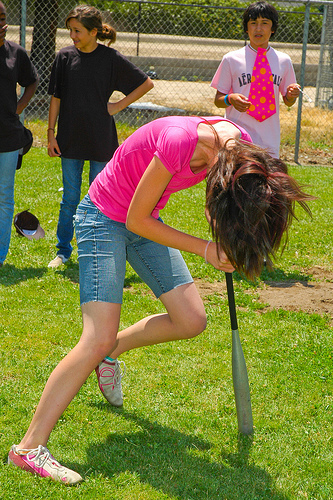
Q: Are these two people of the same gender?
A: No, they are both male and female.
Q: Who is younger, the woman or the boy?
A: The boy is younger than the woman.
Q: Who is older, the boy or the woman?
A: The woman is older than the boy.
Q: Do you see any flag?
A: No, there are no flags.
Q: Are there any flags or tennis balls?
A: No, there are no flags or tennis balls.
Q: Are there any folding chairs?
A: No, there are no folding chairs.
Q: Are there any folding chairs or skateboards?
A: No, there are no folding chairs or skateboards.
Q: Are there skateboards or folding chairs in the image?
A: No, there are no folding chairs or skateboards.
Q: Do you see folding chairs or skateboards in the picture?
A: No, there are no folding chairs or skateboards.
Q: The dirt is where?
A: The dirt is in the grass.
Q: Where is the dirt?
A: The dirt is in the grass.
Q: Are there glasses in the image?
A: No, there are no glasses.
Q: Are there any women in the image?
A: Yes, there is a woman.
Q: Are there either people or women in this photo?
A: Yes, there is a woman.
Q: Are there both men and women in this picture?
A: No, there is a woman but no men.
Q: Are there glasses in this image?
A: No, there are no glasses.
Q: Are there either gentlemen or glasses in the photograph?
A: No, there are no glasses or gentlemen.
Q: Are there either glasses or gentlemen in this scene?
A: No, there are no glasses or gentlemen.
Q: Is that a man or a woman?
A: That is a woman.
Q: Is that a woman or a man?
A: That is a woman.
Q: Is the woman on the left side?
A: Yes, the woman is on the left of the image.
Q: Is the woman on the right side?
A: No, the woman is on the left of the image.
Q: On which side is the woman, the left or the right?
A: The woman is on the left of the image.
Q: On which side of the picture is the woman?
A: The woman is on the left of the image.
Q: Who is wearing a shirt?
A: The woman is wearing a shirt.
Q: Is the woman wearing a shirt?
A: Yes, the woman is wearing a shirt.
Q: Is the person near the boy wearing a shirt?
A: Yes, the woman is wearing a shirt.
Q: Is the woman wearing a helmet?
A: No, the woman is wearing a shirt.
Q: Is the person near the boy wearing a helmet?
A: No, the woman is wearing a shirt.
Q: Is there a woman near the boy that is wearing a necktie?
A: Yes, there is a woman near the boy.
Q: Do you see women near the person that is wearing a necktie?
A: Yes, there is a woman near the boy.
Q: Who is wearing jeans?
A: The woman is wearing jeans.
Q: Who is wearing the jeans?
A: The woman is wearing jeans.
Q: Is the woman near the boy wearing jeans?
A: Yes, the woman is wearing jeans.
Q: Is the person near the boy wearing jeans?
A: Yes, the woman is wearing jeans.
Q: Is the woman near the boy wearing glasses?
A: No, the woman is wearing jeans.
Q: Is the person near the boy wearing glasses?
A: No, the woman is wearing jeans.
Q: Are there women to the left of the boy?
A: Yes, there is a woman to the left of the boy.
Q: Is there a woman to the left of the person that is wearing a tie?
A: Yes, there is a woman to the left of the boy.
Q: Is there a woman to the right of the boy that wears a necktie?
A: No, the woman is to the left of the boy.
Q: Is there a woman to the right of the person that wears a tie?
A: No, the woman is to the left of the boy.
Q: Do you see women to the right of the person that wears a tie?
A: No, the woman is to the left of the boy.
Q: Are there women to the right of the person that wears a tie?
A: No, the woman is to the left of the boy.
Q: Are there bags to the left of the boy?
A: No, there is a woman to the left of the boy.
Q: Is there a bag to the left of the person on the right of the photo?
A: No, there is a woman to the left of the boy.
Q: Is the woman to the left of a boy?
A: Yes, the woman is to the left of a boy.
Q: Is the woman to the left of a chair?
A: No, the woman is to the left of a boy.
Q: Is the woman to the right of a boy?
A: No, the woman is to the left of a boy.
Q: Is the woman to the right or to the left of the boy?
A: The woman is to the left of the boy.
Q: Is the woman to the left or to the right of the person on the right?
A: The woman is to the left of the boy.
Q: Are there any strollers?
A: No, there are no strollers.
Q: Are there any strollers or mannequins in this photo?
A: No, there are no strollers or mannequins.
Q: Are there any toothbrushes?
A: No, there are no toothbrushes.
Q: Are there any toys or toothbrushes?
A: No, there are no toothbrushes or toys.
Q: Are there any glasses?
A: No, there are no glasses.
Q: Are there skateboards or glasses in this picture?
A: No, there are no glasses or skateboards.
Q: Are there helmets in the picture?
A: No, there are no helmets.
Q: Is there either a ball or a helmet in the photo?
A: No, there are no helmets or balls.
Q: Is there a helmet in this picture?
A: No, there are no helmets.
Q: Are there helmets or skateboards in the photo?
A: No, there are no helmets or skateboards.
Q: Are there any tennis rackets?
A: No, there are no tennis rackets.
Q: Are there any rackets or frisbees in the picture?
A: No, there are no rackets or frisbees.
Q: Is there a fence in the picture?
A: Yes, there is a fence.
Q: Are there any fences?
A: Yes, there is a fence.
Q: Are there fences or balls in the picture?
A: Yes, there is a fence.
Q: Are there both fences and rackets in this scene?
A: No, there is a fence but no rackets.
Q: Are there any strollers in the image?
A: No, there are no strollers.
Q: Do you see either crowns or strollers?
A: No, there are no strollers or crowns.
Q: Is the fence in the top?
A: Yes, the fence is in the top of the image.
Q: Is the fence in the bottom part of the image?
A: No, the fence is in the top of the image.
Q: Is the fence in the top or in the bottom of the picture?
A: The fence is in the top of the image.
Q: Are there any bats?
A: Yes, there is a bat.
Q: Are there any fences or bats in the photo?
A: Yes, there is a bat.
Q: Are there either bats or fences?
A: Yes, there is a bat.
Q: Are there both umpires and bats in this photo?
A: No, there is a bat but no umpires.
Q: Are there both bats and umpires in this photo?
A: No, there is a bat but no umpires.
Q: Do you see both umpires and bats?
A: No, there is a bat but no umpires.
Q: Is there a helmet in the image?
A: No, there are no helmets.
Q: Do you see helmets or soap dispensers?
A: No, there are no helmets or soap dispensers.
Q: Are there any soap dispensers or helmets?
A: No, there are no helmets or soap dispensers.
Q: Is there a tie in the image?
A: Yes, there is a tie.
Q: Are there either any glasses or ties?
A: Yes, there is a tie.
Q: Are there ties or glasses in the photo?
A: Yes, there is a tie.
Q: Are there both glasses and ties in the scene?
A: No, there is a tie but no glasses.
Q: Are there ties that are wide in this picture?
A: Yes, there is a wide tie.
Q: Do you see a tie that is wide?
A: Yes, there is a tie that is wide.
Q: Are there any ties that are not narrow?
A: Yes, there is a wide tie.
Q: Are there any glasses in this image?
A: No, there are no glasses.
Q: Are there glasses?
A: No, there are no glasses.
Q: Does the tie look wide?
A: Yes, the tie is wide.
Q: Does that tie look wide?
A: Yes, the tie is wide.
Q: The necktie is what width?
A: The necktie is wide.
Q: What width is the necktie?
A: The necktie is wide.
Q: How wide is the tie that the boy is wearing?
A: The tie is wide.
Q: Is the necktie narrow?
A: No, the necktie is wide.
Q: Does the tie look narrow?
A: No, the tie is wide.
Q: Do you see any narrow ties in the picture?
A: No, there is a tie but it is wide.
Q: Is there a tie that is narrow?
A: No, there is a tie but it is wide.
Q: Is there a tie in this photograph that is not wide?
A: No, there is a tie but it is wide.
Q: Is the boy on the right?
A: Yes, the boy is on the right of the image.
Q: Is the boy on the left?
A: No, the boy is on the right of the image.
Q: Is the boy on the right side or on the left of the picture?
A: The boy is on the right of the image.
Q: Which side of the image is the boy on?
A: The boy is on the right of the image.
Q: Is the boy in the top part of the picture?
A: Yes, the boy is in the top of the image.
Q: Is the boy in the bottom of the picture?
A: No, the boy is in the top of the image.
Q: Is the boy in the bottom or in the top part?
A: The boy is in the top of the image.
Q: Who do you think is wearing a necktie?
A: The boy is wearing a necktie.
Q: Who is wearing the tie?
A: The boy is wearing a necktie.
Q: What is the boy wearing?
A: The boy is wearing a tie.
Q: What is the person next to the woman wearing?
A: The boy is wearing a tie.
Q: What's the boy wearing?
A: The boy is wearing a tie.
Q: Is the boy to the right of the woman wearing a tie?
A: Yes, the boy is wearing a tie.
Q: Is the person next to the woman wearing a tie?
A: Yes, the boy is wearing a tie.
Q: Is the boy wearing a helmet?
A: No, the boy is wearing a tie.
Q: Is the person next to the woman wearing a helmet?
A: No, the boy is wearing a tie.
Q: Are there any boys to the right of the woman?
A: Yes, there is a boy to the right of the woman.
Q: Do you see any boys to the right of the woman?
A: Yes, there is a boy to the right of the woman.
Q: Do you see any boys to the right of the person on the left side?
A: Yes, there is a boy to the right of the woman.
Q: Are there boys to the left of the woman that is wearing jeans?
A: No, the boy is to the right of the woman.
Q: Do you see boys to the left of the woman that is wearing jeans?
A: No, the boy is to the right of the woman.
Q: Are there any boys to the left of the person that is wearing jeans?
A: No, the boy is to the right of the woman.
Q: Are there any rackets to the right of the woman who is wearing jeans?
A: No, there is a boy to the right of the woman.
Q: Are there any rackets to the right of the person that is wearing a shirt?
A: No, there is a boy to the right of the woman.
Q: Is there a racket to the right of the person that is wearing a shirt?
A: No, there is a boy to the right of the woman.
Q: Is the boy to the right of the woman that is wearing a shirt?
A: Yes, the boy is to the right of the woman.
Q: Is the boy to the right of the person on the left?
A: Yes, the boy is to the right of the woman.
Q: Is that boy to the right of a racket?
A: No, the boy is to the right of the woman.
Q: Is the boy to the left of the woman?
A: No, the boy is to the right of the woman.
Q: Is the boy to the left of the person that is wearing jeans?
A: No, the boy is to the right of the woman.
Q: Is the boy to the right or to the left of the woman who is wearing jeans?
A: The boy is to the right of the woman.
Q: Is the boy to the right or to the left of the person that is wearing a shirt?
A: The boy is to the right of the woman.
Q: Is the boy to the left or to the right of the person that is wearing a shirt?
A: The boy is to the right of the woman.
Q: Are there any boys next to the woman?
A: Yes, there is a boy next to the woman.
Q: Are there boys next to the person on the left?
A: Yes, there is a boy next to the woman.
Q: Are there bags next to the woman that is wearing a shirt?
A: No, there is a boy next to the woman.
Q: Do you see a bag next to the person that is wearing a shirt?
A: No, there is a boy next to the woman.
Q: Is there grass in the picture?
A: Yes, there is grass.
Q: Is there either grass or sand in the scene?
A: Yes, there is grass.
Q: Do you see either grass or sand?
A: Yes, there is grass.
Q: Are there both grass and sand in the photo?
A: No, there is grass but no sand.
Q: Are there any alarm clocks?
A: No, there are no alarm clocks.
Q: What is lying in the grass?
A: The cap is lying in the grass.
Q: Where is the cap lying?
A: The cap is lying in the grass.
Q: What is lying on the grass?
A: The cap is lying on the grass.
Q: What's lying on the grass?
A: The cap is lying on the grass.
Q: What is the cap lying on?
A: The cap is lying on the grass.